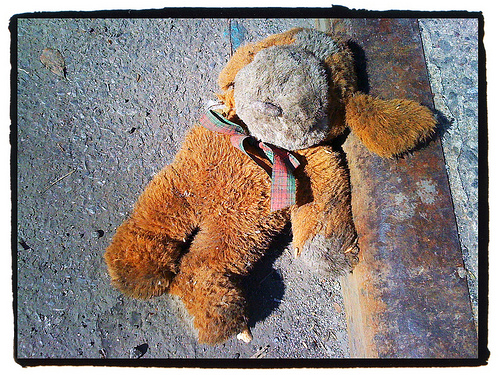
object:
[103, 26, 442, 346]
bear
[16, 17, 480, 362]
ground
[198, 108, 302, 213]
ribbon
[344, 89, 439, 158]
ears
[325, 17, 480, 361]
curb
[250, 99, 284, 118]
mouth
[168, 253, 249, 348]
feet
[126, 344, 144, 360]
pebble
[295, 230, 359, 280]
paws